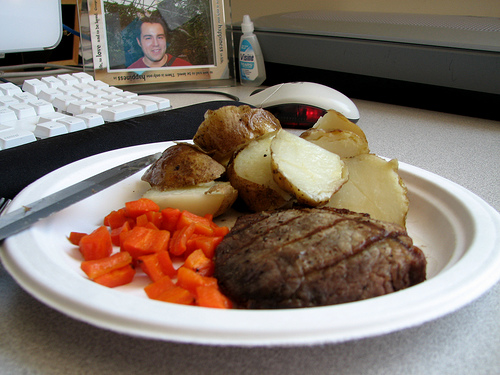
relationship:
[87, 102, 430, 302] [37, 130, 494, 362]
food on plate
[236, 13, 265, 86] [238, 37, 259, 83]
bottle with label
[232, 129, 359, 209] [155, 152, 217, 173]
potato chunks with skin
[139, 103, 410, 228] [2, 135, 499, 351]
potato on plate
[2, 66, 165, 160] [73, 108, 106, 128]
keyboard with key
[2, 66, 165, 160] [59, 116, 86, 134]
keyboard with key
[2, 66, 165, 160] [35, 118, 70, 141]
keyboard with key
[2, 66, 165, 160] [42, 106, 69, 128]
keyboard with key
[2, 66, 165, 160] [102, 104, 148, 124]
keyboard with key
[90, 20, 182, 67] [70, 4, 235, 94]
photo in frame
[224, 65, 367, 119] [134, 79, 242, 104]
computer mouse has tail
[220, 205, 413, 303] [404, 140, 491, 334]
hamburger steak on plate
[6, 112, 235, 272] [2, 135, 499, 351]
knife on plate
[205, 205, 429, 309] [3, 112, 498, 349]
hamburger steak on plate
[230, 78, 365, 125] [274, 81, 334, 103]
computer mouse has white top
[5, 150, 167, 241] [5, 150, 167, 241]
knife has knife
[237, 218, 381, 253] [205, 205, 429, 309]
grill marks on hamburger steak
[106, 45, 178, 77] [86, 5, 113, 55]
words on frame